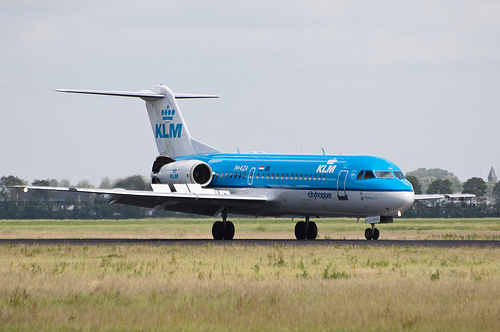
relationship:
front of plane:
[308, 150, 428, 216] [36, 55, 486, 234]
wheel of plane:
[195, 218, 254, 243] [36, 55, 486, 234]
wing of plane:
[17, 174, 267, 217] [36, 55, 486, 234]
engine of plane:
[145, 164, 216, 186] [36, 55, 486, 234]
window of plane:
[256, 170, 268, 180] [36, 55, 486, 234]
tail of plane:
[54, 68, 238, 162] [36, 55, 486, 234]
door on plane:
[333, 169, 351, 206] [36, 55, 486, 234]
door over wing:
[243, 165, 259, 186] [17, 174, 267, 217]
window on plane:
[256, 170, 268, 180] [36, 55, 486, 234]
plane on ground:
[36, 55, 486, 234] [190, 234, 458, 279]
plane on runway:
[36, 55, 486, 234] [1, 231, 497, 244]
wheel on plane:
[195, 218, 254, 243] [36, 55, 486, 234]